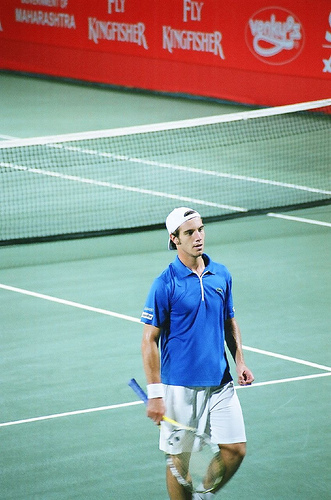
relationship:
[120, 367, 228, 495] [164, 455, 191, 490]
racket has edge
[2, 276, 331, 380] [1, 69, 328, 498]
line in court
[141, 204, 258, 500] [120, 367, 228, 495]
man holding racket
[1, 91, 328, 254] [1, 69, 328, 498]
net tied in middle of court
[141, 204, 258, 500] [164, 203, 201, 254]
man wearing cap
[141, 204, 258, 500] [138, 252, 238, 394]
man inside of shirt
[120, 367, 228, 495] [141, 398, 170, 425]
racket held in hand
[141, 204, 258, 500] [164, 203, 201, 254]
man has cap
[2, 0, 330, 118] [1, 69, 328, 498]
banner on side of court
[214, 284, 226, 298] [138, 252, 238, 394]
alligator on front of shirt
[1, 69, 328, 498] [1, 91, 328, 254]
court has net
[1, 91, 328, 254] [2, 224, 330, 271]
net has shadow